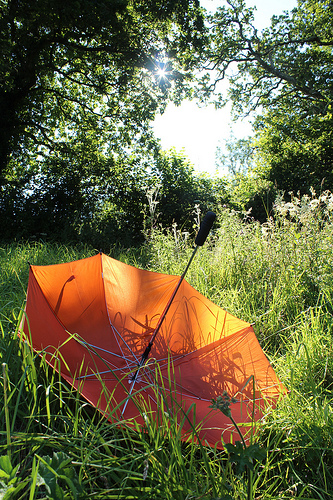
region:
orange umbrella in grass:
[17, 210, 287, 459]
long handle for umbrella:
[192, 205, 214, 245]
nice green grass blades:
[1, 446, 328, 495]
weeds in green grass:
[207, 393, 269, 497]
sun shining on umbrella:
[101, 252, 270, 396]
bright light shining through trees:
[142, 51, 180, 90]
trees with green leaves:
[0, 2, 330, 188]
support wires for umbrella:
[69, 322, 210, 413]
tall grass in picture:
[113, 234, 332, 499]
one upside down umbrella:
[17, 190, 287, 447]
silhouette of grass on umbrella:
[175, 308, 261, 393]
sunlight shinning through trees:
[131, 49, 190, 98]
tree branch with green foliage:
[208, 7, 329, 142]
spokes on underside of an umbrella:
[70, 313, 218, 419]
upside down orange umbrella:
[15, 195, 327, 459]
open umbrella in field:
[23, 199, 307, 467]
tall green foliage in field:
[244, 177, 330, 312]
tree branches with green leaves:
[14, 13, 144, 220]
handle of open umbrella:
[119, 179, 238, 407]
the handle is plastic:
[190, 208, 219, 250]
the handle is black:
[192, 208, 216, 249]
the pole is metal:
[152, 245, 194, 339]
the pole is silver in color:
[151, 247, 195, 338]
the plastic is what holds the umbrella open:
[136, 339, 155, 362]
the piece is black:
[138, 339, 155, 360]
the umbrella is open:
[24, 247, 292, 462]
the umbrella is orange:
[23, 251, 287, 458]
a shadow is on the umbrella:
[136, 268, 161, 320]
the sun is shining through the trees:
[149, 66, 169, 81]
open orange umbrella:
[17, 202, 280, 453]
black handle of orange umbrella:
[141, 205, 222, 372]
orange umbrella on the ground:
[15, 216, 310, 460]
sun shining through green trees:
[126, 1, 200, 120]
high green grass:
[6, 352, 330, 498]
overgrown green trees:
[8, 1, 148, 240]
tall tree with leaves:
[200, 2, 331, 187]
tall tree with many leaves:
[11, 1, 123, 248]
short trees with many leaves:
[115, 155, 261, 230]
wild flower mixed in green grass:
[208, 389, 259, 490]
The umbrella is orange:
[26, 239, 296, 439]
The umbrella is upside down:
[23, 205, 294, 444]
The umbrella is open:
[40, 209, 283, 439]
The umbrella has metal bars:
[71, 309, 199, 416]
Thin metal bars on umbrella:
[69, 319, 207, 416]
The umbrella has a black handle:
[180, 204, 248, 263]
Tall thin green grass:
[0, 257, 322, 497]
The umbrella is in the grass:
[22, 227, 307, 450]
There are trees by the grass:
[29, 23, 291, 225]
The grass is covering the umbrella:
[13, 201, 305, 451]